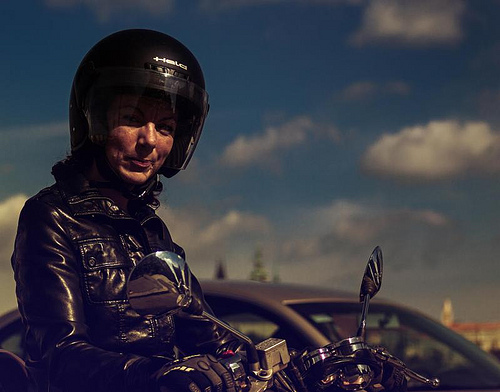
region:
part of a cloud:
[350, 218, 352, 221]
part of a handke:
[350, 323, 376, 369]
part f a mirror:
[150, 280, 196, 362]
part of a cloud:
[393, 140, 431, 203]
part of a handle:
[355, 298, 381, 328]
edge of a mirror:
[118, 293, 137, 318]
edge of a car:
[298, 295, 312, 302]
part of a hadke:
[344, 296, 370, 343]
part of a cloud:
[392, 205, 428, 256]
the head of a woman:
[92, 83, 221, 196]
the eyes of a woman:
[109, 112, 181, 132]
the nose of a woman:
[129, 104, 176, 154]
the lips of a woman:
[127, 152, 154, 183]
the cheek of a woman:
[93, 127, 143, 164]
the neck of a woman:
[77, 149, 134, 212]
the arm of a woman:
[29, 197, 160, 367]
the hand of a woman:
[166, 337, 253, 381]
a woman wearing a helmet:
[50, 57, 238, 204]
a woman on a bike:
[51, 87, 299, 354]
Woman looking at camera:
[11, 24, 481, 390]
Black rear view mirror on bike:
[338, 246, 407, 356]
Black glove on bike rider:
[132, 338, 254, 389]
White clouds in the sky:
[3, 1, 498, 306]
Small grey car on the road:
[2, 272, 498, 390]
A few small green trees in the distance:
[200, 244, 309, 287]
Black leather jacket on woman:
[2, 165, 250, 390]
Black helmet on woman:
[57, 16, 222, 203]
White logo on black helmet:
[146, 49, 193, 76]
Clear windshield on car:
[284, 283, 498, 390]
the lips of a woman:
[119, 149, 171, 179]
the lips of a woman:
[116, 163, 160, 195]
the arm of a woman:
[10, 193, 105, 365]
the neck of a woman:
[62, 143, 162, 223]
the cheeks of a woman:
[96, 117, 144, 170]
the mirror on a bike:
[114, 211, 255, 342]